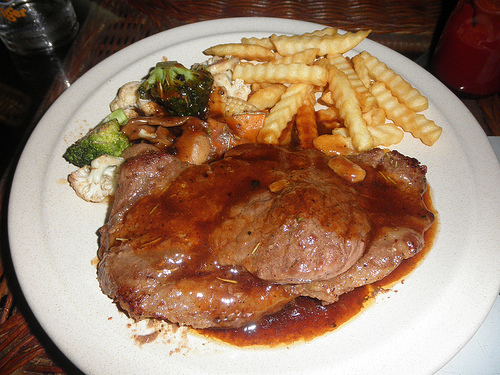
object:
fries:
[268, 28, 374, 56]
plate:
[7, 16, 500, 375]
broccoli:
[133, 61, 216, 120]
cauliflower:
[67, 155, 126, 203]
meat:
[96, 143, 434, 329]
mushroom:
[118, 116, 212, 166]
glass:
[0, 0, 81, 58]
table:
[1, 2, 499, 374]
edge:
[156, 16, 316, 35]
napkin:
[485, 136, 499, 157]